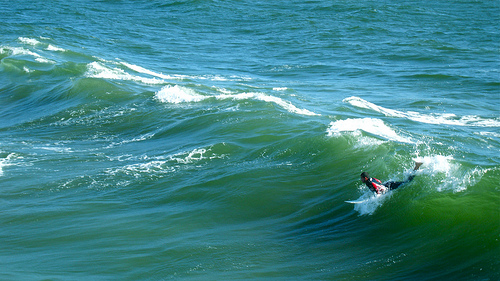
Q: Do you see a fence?
A: No, there are no fences.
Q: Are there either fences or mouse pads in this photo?
A: No, there are no fences or mouse pads.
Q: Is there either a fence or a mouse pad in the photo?
A: No, there are no fences or mouse pads.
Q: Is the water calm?
A: Yes, the water is calm.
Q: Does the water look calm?
A: Yes, the water is calm.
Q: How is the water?
A: The water is calm.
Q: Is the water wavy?
A: No, the water is calm.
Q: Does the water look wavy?
A: No, the water is calm.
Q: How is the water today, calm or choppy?
A: The water is calm.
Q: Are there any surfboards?
A: Yes, there is a surfboard.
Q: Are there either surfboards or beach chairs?
A: Yes, there is a surfboard.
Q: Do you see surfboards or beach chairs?
A: Yes, there is a surfboard.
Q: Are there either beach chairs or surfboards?
A: Yes, there is a surfboard.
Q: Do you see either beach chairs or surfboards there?
A: Yes, there is a surfboard.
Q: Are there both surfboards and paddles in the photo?
A: No, there is a surfboard but no paddles.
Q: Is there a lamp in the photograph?
A: No, there are no lamps.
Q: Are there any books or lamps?
A: No, there are no lamps or books.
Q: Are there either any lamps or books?
A: No, there are no lamps or books.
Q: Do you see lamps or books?
A: No, there are no lamps or books.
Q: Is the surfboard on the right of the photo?
A: Yes, the surfboard is on the right of the image.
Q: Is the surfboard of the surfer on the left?
A: No, the surf board is on the right of the image.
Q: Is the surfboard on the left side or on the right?
A: The surfboard is on the right of the image.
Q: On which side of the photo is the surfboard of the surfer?
A: The surfboard is on the right of the image.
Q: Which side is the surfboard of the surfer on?
A: The surfboard is on the right of the image.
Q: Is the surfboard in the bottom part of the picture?
A: Yes, the surfboard is in the bottom of the image.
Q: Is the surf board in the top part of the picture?
A: No, the surf board is in the bottom of the image.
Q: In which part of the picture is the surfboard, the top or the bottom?
A: The surfboard is in the bottom of the image.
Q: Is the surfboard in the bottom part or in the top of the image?
A: The surfboard is in the bottom of the image.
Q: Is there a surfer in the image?
A: Yes, there is a surfer.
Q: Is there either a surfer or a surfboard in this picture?
A: Yes, there is a surfer.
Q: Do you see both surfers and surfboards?
A: Yes, there are both a surfer and a surfboard.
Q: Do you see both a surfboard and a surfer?
A: Yes, there are both a surfer and a surfboard.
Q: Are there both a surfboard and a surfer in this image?
A: Yes, there are both a surfer and a surfboard.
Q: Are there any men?
A: No, there are no men.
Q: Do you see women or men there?
A: No, there are no men or women.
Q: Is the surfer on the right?
A: Yes, the surfer is on the right of the image.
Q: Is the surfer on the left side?
A: No, the surfer is on the right of the image.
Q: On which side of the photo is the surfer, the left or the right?
A: The surfer is on the right of the image.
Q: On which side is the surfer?
A: The surfer is on the right of the image.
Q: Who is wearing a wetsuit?
A: The surfer is wearing a wetsuit.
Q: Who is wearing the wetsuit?
A: The surfer is wearing a wetsuit.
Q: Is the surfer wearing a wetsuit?
A: Yes, the surfer is wearing a wetsuit.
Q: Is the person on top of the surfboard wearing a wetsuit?
A: Yes, the surfer is wearing a wetsuit.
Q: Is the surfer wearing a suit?
A: No, the surfer is wearing a wetsuit.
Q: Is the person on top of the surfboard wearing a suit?
A: No, the surfer is wearing a wetsuit.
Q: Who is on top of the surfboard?
A: The surfer is on top of the surfboard.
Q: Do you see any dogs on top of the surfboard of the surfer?
A: No, there is a surfer on top of the surfboard.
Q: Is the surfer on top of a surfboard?
A: Yes, the surfer is on top of a surfboard.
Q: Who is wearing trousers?
A: The surfer is wearing trousers.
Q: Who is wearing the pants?
A: The surfer is wearing trousers.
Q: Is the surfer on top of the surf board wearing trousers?
A: Yes, the surfer is wearing trousers.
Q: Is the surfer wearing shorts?
A: No, the surfer is wearing trousers.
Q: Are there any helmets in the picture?
A: No, there are no helmets.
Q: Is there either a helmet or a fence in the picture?
A: No, there are no helmets or fences.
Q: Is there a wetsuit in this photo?
A: Yes, there is a wetsuit.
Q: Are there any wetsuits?
A: Yes, there is a wetsuit.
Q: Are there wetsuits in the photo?
A: Yes, there is a wetsuit.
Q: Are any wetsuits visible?
A: Yes, there is a wetsuit.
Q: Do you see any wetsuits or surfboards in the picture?
A: Yes, there is a wetsuit.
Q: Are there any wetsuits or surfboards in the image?
A: Yes, there is a wetsuit.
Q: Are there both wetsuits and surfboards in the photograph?
A: Yes, there are both a wetsuit and a surfboard.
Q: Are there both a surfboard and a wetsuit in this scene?
A: Yes, there are both a wetsuit and a surfboard.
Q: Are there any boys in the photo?
A: No, there are no boys.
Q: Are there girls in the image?
A: No, there are no girls.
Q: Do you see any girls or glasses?
A: No, there are no girls or glasses.